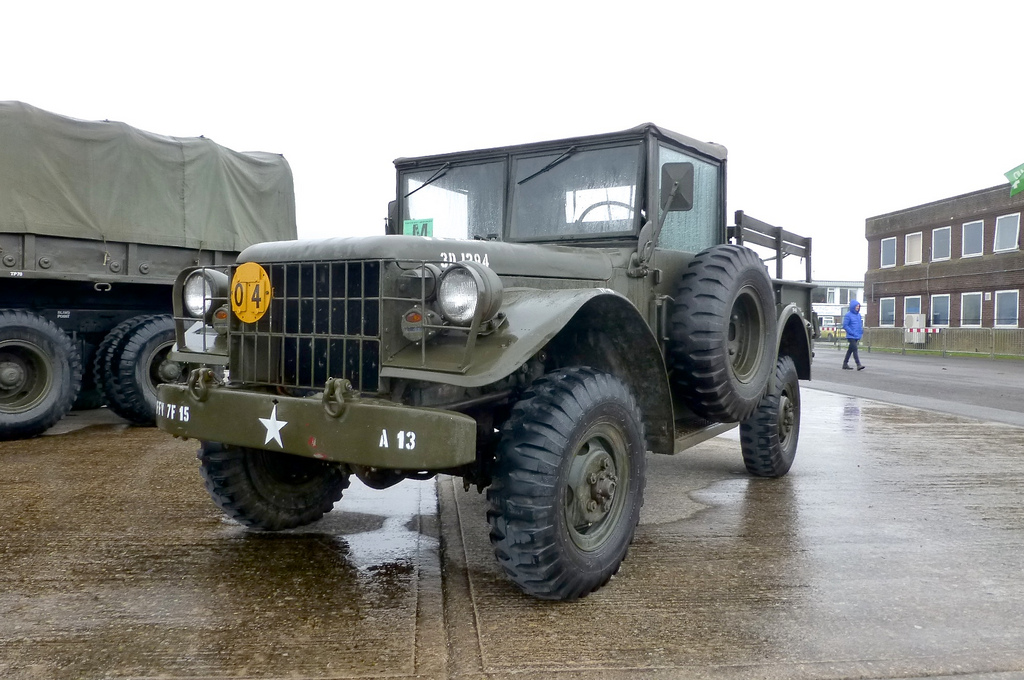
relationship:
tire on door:
[661, 242, 768, 405] [635, 249, 795, 444]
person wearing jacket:
[819, 283, 884, 411] [828, 314, 868, 341]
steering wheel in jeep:
[566, 180, 646, 248] [171, 109, 822, 594]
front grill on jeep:
[191, 232, 397, 425] [171, 109, 822, 594]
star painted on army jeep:
[244, 392, 297, 453] [150, 121, 818, 602]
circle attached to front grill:
[214, 255, 277, 344] [153, 235, 481, 470]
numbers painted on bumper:
[394, 420, 427, 455] [132, 376, 476, 500]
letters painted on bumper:
[355, 409, 392, 453] [132, 376, 476, 500]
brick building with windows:
[858, 188, 1014, 342] [873, 219, 1001, 263]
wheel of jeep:
[169, 422, 353, 556] [171, 109, 822, 594]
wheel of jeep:
[445, 342, 666, 610] [171, 109, 822, 594]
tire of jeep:
[670, 242, 779, 424] [165, 132, 805, 610]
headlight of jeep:
[163, 258, 243, 332] [171, 109, 822, 594]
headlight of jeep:
[420, 247, 500, 332] [171, 109, 822, 594]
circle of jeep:
[230, 260, 273, 323] [121, 109, 834, 656]